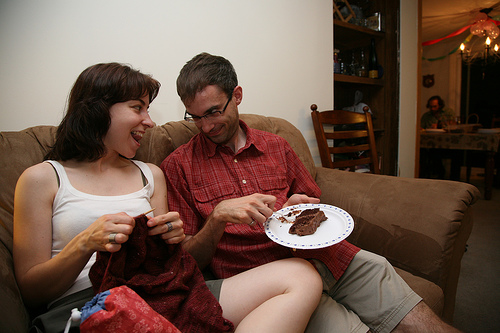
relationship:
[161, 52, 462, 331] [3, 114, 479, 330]
man sitting on sofa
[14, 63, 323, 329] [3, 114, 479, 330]
woman sitting on sofa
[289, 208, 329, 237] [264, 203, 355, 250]
food on plate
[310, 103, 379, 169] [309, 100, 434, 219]
backing of chair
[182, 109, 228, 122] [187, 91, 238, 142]
glasses are on face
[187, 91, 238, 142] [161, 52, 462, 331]
face of man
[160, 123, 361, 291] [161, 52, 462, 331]
shirt worn on man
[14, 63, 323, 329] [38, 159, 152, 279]
woman wearing tank top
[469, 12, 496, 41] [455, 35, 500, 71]
balloons are hanging from light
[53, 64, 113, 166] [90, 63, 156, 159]
hair on head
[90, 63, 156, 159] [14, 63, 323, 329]
head of woman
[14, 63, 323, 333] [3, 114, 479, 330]
woman are sitting on sofa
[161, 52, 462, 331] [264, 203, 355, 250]
man holding plate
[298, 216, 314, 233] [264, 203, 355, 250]
cake sitting on plate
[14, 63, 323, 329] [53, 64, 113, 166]
woman has hair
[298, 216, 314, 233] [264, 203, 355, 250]
desert sitting on plate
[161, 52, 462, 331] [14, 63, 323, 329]
man looking at woman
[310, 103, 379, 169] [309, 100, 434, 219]
back of chair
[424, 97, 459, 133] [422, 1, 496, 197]
man sitting in room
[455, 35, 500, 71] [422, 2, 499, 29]
light attached to ceiling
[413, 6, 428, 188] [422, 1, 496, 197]
doorway to room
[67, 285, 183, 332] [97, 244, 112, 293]
bag containing yarn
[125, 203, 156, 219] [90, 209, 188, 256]
needled used to knit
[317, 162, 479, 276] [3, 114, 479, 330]
arm of sofa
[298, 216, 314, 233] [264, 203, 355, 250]
cake on plate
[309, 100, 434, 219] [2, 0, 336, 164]
chair against wall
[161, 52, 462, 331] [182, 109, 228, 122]
man with glasses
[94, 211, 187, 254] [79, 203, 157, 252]
hands with needle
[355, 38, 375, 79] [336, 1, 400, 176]
bottles are sitting on shelf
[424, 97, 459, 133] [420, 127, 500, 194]
man sitting at table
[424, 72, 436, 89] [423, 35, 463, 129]
plaque hanging on wall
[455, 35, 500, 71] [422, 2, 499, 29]
chandelier attached to ceiling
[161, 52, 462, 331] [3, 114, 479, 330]
man seated on sofa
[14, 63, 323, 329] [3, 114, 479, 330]
woman seated on sofa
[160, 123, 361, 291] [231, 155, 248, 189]
shirt has buttons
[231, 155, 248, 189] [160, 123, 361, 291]
buttons are on shirt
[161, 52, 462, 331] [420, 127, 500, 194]
man sitting at table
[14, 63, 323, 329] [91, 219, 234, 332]
woman crocheting blanket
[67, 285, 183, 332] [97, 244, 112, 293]
bag of yarn